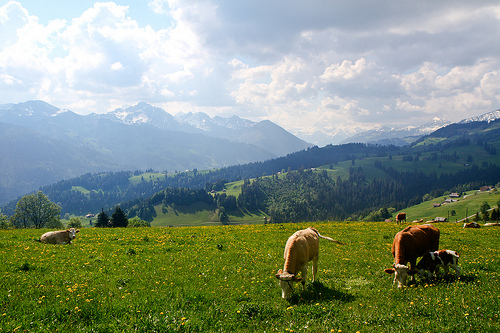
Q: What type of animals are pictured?
A: Cows.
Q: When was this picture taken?
A: Daytime.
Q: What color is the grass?
A: Green.